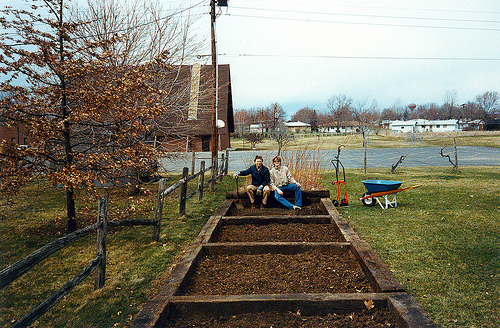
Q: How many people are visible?
A: Two.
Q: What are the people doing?
A: Sitting.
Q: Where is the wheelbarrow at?
A: On the grass.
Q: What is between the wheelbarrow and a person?
A: Dolly.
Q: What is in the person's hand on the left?
A: Shovel.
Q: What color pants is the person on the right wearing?
A: Blue.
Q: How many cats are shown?
A: Zero.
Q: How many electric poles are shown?
A: Two.